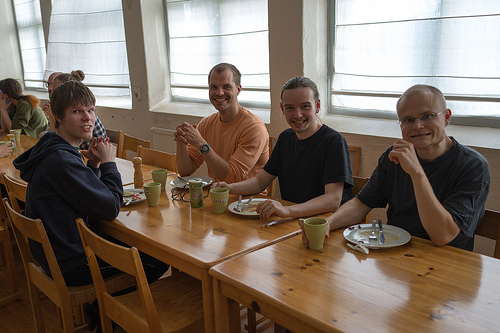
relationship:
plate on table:
[303, 192, 418, 261] [19, 89, 494, 318]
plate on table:
[227, 198, 282, 216] [0, 128, 498, 330]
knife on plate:
[264, 212, 283, 227] [343, 219, 412, 248]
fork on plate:
[368, 219, 377, 245] [343, 219, 412, 248]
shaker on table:
[149, 179, 230, 240] [199, 200, 381, 304]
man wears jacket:
[11, 82, 167, 277] [17, 128, 120, 268]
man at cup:
[174, 62, 270, 194] [210, 187, 227, 210]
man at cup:
[211, 77, 353, 222] [297, 217, 327, 252]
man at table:
[301, 84, 490, 252] [102, 169, 498, 327]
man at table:
[211, 77, 353, 222] [102, 169, 498, 327]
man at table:
[174, 62, 270, 194] [102, 169, 498, 327]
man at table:
[20, 82, 167, 277] [102, 169, 498, 327]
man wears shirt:
[166, 61, 271, 194] [183, 105, 271, 187]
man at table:
[166, 61, 271, 194] [101, 157, 311, 254]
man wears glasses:
[301, 84, 490, 252] [396, 107, 448, 124]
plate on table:
[224, 194, 273, 216] [262, 226, 496, 331]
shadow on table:
[375, 237, 490, 328] [209, 223, 497, 330]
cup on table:
[272, 190, 340, 256] [114, 200, 498, 330]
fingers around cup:
[299, 220, 310, 248] [297, 216, 328, 249]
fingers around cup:
[325, 228, 331, 238] [297, 216, 328, 249]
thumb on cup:
[324, 221, 331, 239] [297, 216, 328, 249]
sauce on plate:
[381, 229, 399, 242] [341, 196, 408, 291]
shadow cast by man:
[375, 237, 483, 332] [301, 82, 489, 259]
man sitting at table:
[301, 82, 489, 259] [0, 128, 498, 330]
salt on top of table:
[115, 154, 150, 194] [0, 128, 498, 330]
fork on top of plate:
[368, 219, 377, 245] [338, 212, 418, 252]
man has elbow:
[301, 84, 490, 252] [421, 198, 465, 257]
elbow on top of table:
[421, 198, 465, 257] [359, 250, 469, 320]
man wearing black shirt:
[301, 84, 490, 252] [354, 135, 491, 252]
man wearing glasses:
[301, 82, 489, 259] [392, 105, 449, 127]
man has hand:
[301, 84, 490, 252] [295, 215, 312, 252]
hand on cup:
[295, 215, 312, 252] [296, 212, 328, 254]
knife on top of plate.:
[376, 217, 386, 248] [343, 221, 409, 247]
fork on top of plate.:
[369, 221, 376, 245] [343, 221, 409, 247]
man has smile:
[166, 61, 271, 194] [214, 95, 227, 101]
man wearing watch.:
[174, 62, 270, 194] [195, 138, 217, 159]